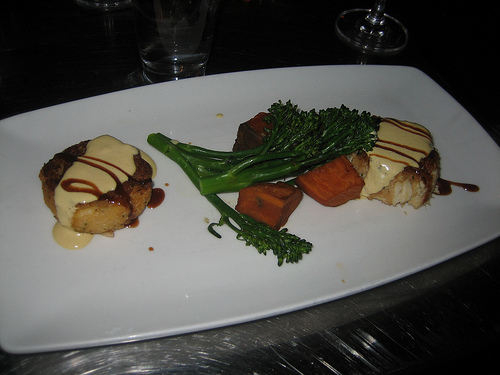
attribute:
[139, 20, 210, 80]
cup — glass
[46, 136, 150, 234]
cake — fish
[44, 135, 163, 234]
cake — fish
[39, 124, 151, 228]
sauce — white, brown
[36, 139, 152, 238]
cake — fish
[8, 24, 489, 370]
table — black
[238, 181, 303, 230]
potato — sweet, sliced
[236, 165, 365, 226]
potatoes — sweet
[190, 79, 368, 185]
broccoli — some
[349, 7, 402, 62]
glass — wine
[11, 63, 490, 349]
plate — white, large, one, flat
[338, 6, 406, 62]
glass — wine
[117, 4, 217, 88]
glass — empty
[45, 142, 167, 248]
food — brown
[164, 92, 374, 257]
vegetable — green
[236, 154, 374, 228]
potatoes — orange 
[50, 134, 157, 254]
sauce — white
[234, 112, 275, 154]
potato — roasted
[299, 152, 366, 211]
potato — roasted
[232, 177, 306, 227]
potato — roasted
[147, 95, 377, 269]
broccoli — green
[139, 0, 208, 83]
glass — empty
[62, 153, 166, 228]
sauce — dark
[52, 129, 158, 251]
cream — brown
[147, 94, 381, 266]
veggies — green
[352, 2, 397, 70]
glass — shiny